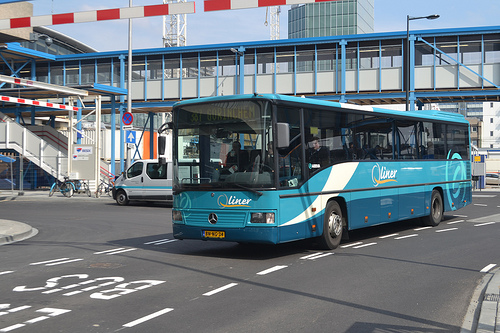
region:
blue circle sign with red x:
[117, 105, 135, 128]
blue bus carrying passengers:
[168, 75, 479, 249]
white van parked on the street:
[113, 145, 172, 203]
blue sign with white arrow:
[119, 126, 137, 143]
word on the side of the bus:
[358, 161, 413, 190]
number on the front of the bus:
[179, 98, 248, 126]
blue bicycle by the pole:
[43, 169, 82, 201]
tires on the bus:
[303, 168, 451, 253]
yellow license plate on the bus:
[200, 224, 231, 240]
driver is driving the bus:
[250, 129, 282, 180]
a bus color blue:
[153, 84, 480, 247]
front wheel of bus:
[313, 191, 355, 254]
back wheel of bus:
[424, 185, 447, 229]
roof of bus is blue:
[163, 81, 473, 124]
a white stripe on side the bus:
[260, 152, 482, 233]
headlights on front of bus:
[164, 204, 282, 229]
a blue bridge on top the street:
[89, 19, 497, 100]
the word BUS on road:
[11, 259, 161, 312]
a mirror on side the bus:
[268, 113, 294, 156]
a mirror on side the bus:
[151, 116, 173, 166]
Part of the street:
[336, 304, 397, 320]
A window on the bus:
[166, 94, 281, 194]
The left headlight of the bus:
[247, 208, 278, 226]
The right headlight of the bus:
[168, 205, 183, 222]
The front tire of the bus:
[321, 196, 346, 251]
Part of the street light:
[427, 14, 438, 19]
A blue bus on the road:
[164, 91, 484, 253]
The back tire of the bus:
[419, 186, 446, 228]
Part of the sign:
[125, 116, 130, 123]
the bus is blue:
[169, 89, 475, 256]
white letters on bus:
[369, 159, 398, 187]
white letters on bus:
[225, 190, 256, 210]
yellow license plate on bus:
[196, 224, 226, 242]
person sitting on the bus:
[221, 136, 240, 168]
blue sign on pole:
[119, 109, 136, 129]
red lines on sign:
[119, 109, 137, 126]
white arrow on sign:
[125, 130, 136, 144]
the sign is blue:
[122, 128, 137, 145]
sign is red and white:
[0, 83, 85, 116]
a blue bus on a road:
[166, 90, 471, 252]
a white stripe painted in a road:
[122, 302, 175, 328]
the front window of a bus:
[174, 97, 264, 187]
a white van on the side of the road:
[111, 155, 224, 208]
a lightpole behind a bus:
[402, 9, 442, 112]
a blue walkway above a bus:
[38, 22, 497, 116]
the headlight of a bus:
[247, 208, 277, 225]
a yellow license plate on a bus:
[201, 227, 227, 240]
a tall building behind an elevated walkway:
[284, 0, 377, 38]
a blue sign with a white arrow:
[122, 125, 138, 147]